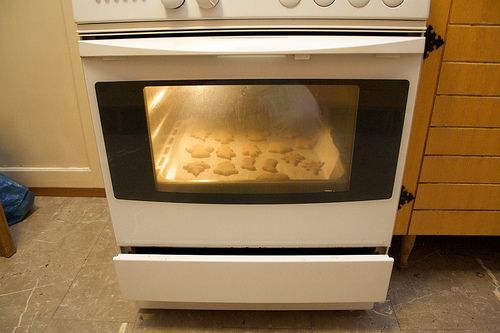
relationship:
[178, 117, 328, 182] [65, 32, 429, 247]
cookies in white oven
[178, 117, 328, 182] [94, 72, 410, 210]
cookies in oven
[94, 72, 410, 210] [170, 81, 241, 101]
oven with light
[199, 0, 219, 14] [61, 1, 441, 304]
knobs on stove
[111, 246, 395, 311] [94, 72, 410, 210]
drawer below oven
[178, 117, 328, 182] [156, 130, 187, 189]
cookies on silver tray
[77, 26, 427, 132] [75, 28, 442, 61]
window in door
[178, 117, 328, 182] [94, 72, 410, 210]
cookies inside oven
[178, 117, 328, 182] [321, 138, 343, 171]
cookies on wax paper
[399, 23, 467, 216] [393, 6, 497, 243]
hinges on a cabinets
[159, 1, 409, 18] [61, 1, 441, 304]
knobs on stove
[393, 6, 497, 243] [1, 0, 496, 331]
cabinets in a kitchen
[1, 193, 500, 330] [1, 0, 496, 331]
linoleum floor in a kitchen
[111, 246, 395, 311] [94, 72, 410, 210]
drawer on oven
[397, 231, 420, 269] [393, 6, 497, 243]
wood leg holding up a cabinets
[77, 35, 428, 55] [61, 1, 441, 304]
handle on a stove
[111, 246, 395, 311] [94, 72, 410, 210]
drawer under oven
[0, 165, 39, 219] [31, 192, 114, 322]
bag on floor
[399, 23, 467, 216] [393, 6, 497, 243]
hinges on cabinets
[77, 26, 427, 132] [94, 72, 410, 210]
window on oven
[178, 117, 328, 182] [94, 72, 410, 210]
cookies in a oven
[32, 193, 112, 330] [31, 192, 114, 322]
tile on floor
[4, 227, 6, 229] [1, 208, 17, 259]
wooden chair leg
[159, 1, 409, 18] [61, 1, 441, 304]
control on stove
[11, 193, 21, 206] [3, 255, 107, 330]
fabric on ground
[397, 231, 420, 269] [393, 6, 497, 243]
wood leg on cabinets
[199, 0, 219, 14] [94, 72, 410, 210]
knobs on oven